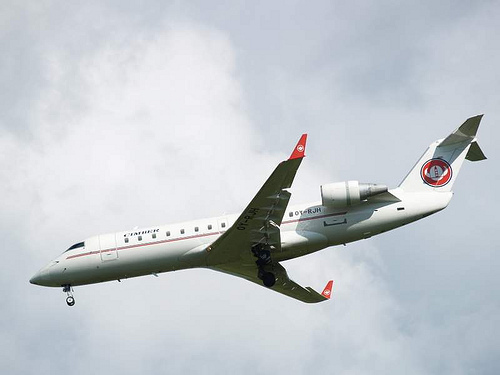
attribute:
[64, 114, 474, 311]
plane — white, red, grey, flying, large, huge, landing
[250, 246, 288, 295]
wheels — out, black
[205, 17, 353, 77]
sky — cloudy